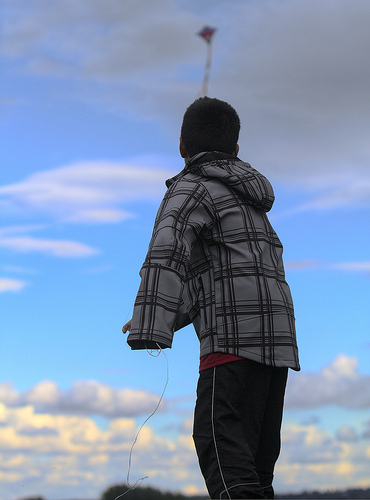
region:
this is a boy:
[127, 96, 277, 471]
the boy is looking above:
[109, 89, 290, 495]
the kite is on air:
[186, 17, 229, 101]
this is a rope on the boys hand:
[107, 348, 175, 493]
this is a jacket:
[133, 163, 289, 355]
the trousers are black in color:
[209, 379, 281, 493]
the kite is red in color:
[196, 24, 220, 44]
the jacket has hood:
[211, 168, 262, 196]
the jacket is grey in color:
[196, 174, 257, 332]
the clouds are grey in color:
[1, 11, 160, 96]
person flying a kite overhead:
[107, 13, 314, 451]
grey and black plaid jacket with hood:
[113, 141, 321, 387]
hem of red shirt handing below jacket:
[192, 338, 246, 377]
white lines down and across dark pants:
[190, 368, 282, 499]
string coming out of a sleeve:
[106, 305, 183, 468]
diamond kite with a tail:
[189, 17, 222, 104]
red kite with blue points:
[183, 19, 222, 48]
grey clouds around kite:
[120, 15, 266, 66]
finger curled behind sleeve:
[104, 291, 157, 351]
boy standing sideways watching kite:
[112, 14, 312, 479]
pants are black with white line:
[193, 344, 298, 498]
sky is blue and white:
[14, 348, 143, 498]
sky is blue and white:
[295, 318, 367, 444]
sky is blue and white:
[271, 350, 365, 490]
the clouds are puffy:
[7, 161, 162, 232]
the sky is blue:
[8, 84, 363, 357]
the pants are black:
[202, 350, 286, 495]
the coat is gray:
[173, 178, 297, 360]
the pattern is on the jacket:
[216, 232, 236, 343]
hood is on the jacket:
[200, 154, 276, 205]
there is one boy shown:
[183, 103, 293, 491]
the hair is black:
[188, 98, 236, 161]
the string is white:
[145, 339, 170, 374]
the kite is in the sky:
[200, 26, 216, 45]